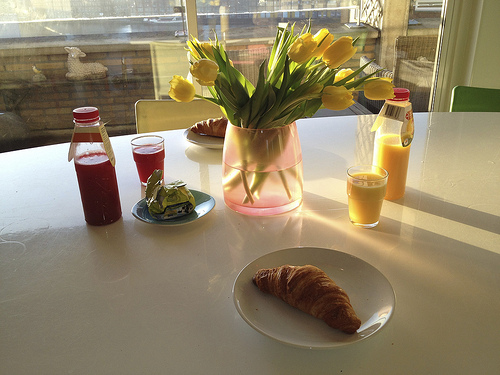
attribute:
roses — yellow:
[183, 53, 247, 103]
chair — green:
[444, 82, 499, 116]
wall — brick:
[11, 60, 142, 104]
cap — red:
[386, 87, 413, 104]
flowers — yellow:
[164, 21, 401, 124]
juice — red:
[75, 152, 121, 227]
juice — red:
[74, 131, 115, 222]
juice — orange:
[347, 178, 387, 218]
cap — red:
[383, 70, 431, 106]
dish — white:
[212, 232, 404, 357]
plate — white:
[220, 241, 409, 351]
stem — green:
[248, 52, 283, 121]